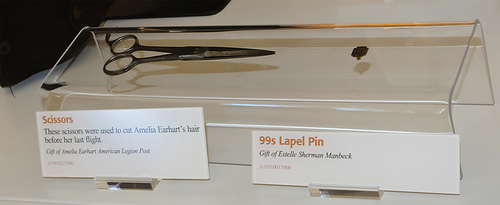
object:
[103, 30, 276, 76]
scissors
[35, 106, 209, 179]
card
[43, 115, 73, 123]
text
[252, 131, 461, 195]
card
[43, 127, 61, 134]
text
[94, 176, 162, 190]
card holder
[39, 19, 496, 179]
display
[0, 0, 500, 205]
table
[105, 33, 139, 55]
handle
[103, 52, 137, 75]
handle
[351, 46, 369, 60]
lapel pin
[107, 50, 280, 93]
reflection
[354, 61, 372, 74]
reflection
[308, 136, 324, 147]
text